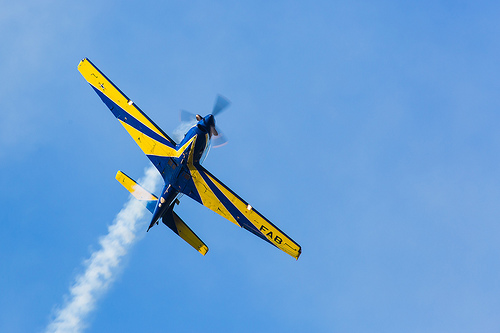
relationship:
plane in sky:
[74, 55, 301, 259] [1, 0, 496, 330]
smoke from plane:
[41, 190, 195, 301] [46, 49, 324, 259]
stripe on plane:
[164, 140, 204, 200] [74, 55, 301, 259]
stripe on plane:
[137, 198, 159, 215] [74, 56, 302, 261]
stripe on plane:
[161, 206, 179, 235] [74, 55, 301, 259]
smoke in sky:
[41, 164, 168, 332] [1, 0, 499, 332]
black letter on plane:
[266, 228, 274, 243] [74, 55, 301, 259]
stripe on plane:
[191, 162, 271, 244] [74, 55, 301, 259]